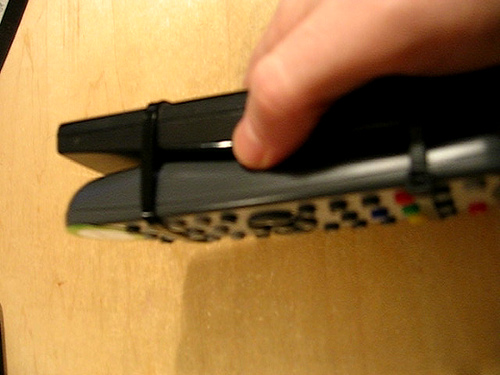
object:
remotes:
[87, 161, 194, 227]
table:
[0, 1, 499, 374]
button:
[393, 192, 419, 217]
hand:
[231, 0, 499, 170]